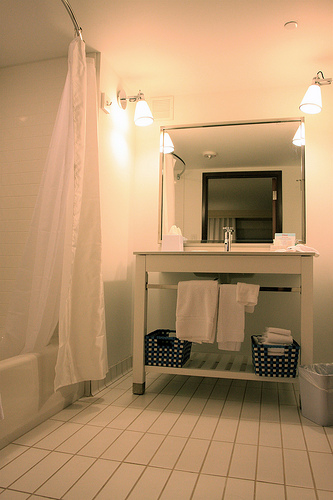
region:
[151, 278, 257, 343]
White towels hanging on a tension rod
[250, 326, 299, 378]
Folded towels in a blue and white basket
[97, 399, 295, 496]
White tiled floor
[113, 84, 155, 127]
Clear sconce with silver fixture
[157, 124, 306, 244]
Mirror facing a brown door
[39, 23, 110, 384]
White shower curtain on a silver rod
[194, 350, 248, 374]
White wooden slats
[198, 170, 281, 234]
Reflection of an open door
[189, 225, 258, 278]
White sink with silver hardware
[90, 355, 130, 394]
White wall with white tile baseboard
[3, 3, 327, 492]
a very clean and bright bathroom scene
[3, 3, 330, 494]
a bathroom that is almost completely white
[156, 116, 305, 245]
bathroom mirror with a silver frame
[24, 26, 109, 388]
white shower curtain hanging up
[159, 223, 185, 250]
white tissue box with tissues sticking out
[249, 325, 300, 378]
a black woven basket filled with towels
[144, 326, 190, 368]
an empty black woven basket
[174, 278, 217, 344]
a large white bath towel hanging on the rack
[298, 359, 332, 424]
a grey trash bin with a plastic bag in it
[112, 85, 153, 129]
a bathroom light with a silver wall attachment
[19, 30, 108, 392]
Shower curtain hung on rail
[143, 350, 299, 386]
Shelf in bathroom sink stand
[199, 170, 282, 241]
Reflection of the door in the mirror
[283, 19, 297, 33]
Cover for an electrical box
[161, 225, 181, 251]
Box of tissues sitting on a countertop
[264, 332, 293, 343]
Folded bath towel in a basket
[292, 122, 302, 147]
Reflection of wall lamp in the mirror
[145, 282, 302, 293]
Round rod used to hang towels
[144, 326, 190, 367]
Empty basket on a shelf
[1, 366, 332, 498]
White tiled bathroom floor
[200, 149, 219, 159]
Smoke alarm hung on the ceiling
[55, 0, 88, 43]
Rail for shower curtain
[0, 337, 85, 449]
Side of a white bathtub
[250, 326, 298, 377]
Basket full of hand towels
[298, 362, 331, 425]
Trashcan in the bathroom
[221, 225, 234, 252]
Faucet on bathroom sink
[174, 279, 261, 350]
Hand towels hanging on the sink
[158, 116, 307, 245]
Mirror on bathroom wall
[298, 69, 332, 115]
Light hanging from wall in the bathroom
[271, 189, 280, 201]
Reflection of a door hinge in the mirror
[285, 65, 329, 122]
a light on right side of bathroom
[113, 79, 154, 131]
a light on left side of bathroom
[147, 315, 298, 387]
two baskets under a table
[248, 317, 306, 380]
basket with white towels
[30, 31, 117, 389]
white curtain in a bathroom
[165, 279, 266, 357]
three towels are hunging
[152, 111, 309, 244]
a mirror over a table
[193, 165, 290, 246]
a door reflected in a mirror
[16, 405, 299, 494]
floor is covered with white tiles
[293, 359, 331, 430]
a trash can color gray